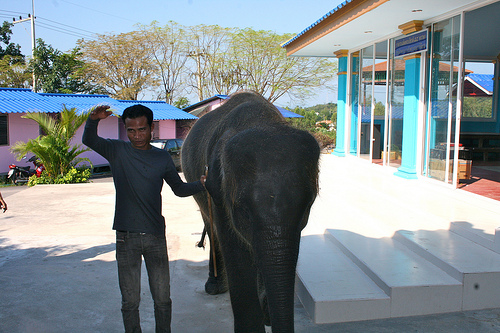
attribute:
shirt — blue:
[79, 117, 198, 238]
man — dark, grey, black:
[81, 100, 209, 326]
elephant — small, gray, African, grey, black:
[175, 85, 322, 329]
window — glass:
[345, 55, 371, 158]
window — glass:
[382, 34, 405, 169]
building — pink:
[2, 83, 202, 183]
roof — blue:
[0, 86, 200, 125]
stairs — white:
[292, 152, 496, 326]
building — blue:
[279, 3, 498, 213]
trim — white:
[412, 51, 427, 180]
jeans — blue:
[112, 227, 172, 329]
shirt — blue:
[82, 118, 208, 228]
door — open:
[456, 0, 497, 196]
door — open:
[451, 0, 498, 200]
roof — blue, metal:
[0, 83, 203, 123]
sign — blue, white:
[389, 23, 434, 61]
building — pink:
[2, 82, 201, 174]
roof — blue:
[1, 90, 199, 112]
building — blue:
[283, 5, 499, 236]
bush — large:
[6, 102, 91, 189]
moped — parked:
[5, 151, 44, 186]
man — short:
[78, 100, 196, 330]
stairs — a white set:
[298, 193, 484, 324]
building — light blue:
[280, 15, 483, 184]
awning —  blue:
[0, 92, 193, 121]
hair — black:
[120, 105, 152, 118]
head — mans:
[115, 102, 157, 152]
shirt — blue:
[75, 117, 205, 231]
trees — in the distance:
[68, 17, 296, 99]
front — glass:
[342, 10, 478, 196]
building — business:
[274, 2, 484, 192]